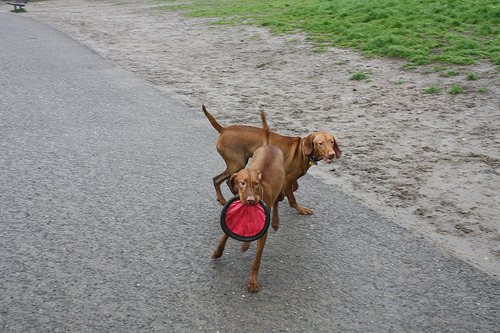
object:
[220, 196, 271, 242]
frisbee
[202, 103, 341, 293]
two dogs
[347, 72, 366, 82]
grass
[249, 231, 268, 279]
front leg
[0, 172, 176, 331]
asphalt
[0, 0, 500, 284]
brown dirt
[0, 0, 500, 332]
road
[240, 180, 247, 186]
eye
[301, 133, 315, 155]
ear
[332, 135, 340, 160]
ear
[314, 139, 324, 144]
eye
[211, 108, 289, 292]
dog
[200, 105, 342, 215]
dog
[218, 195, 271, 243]
ring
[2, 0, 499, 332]
ground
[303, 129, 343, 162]
head